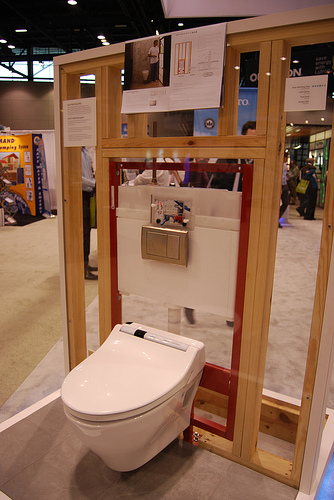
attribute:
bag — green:
[292, 177, 310, 195]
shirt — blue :
[75, 141, 105, 203]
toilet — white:
[48, 312, 215, 479]